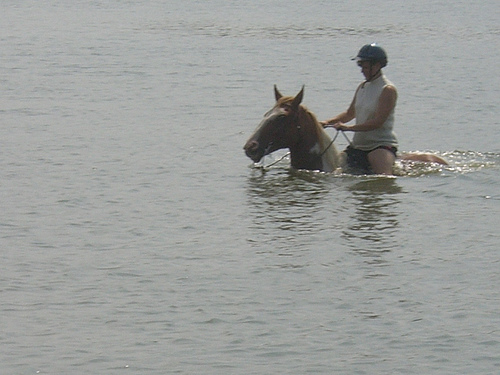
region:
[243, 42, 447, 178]
a horse and rider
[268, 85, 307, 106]
the ears of a horse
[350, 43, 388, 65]
a dark colored safety helmet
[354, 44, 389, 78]
a woman's head with a helmet on it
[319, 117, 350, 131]
reins in a woman's hands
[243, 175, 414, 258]
reflection in the water of a horse and rider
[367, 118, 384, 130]
a woman's left elbow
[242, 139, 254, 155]
the nose of a horse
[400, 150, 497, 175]
a ripple in the water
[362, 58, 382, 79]
the chin strap of a helmet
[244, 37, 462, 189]
horse and rider are in the water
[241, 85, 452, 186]
horse is in the water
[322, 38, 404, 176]
rider is in the water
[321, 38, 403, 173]
rider is wearing a helmet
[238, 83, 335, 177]
horse is wearing a halter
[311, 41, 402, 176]
rider hangs on to the reigns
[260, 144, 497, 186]
ripples in the water are caused by the horse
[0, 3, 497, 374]
water surrounds the horse and rider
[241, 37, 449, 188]
horse and rider are getting wet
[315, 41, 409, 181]
human is wearing shorts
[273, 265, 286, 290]
part of the sky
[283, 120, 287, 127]
eye of a horse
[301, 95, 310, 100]
ear of a horse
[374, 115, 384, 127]
part of a shirt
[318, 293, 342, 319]
part of a wave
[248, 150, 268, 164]
mouth of a horse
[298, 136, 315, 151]
part of a horse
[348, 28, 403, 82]
helmet on the person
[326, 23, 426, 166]
person on the horse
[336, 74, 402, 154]
white shirt on the person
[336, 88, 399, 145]
arm of the person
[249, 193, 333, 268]
water next to horse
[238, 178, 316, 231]
reflection in the water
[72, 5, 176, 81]
water in the background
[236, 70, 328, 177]
head of the horse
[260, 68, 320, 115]
ears of the horse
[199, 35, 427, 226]
lady riding a horse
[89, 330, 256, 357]
Clear mass of water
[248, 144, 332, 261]
Black wavy water mass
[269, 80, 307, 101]
Two short horse ears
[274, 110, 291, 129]
A big black eye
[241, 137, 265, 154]
Big hollow horse nostrils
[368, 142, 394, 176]
A muscular white thigh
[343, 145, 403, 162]
Short black colored pant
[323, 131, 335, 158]
Long narrow navigating rope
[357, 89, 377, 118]
White sleeveless light top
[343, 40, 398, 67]
Blue colored protection cap